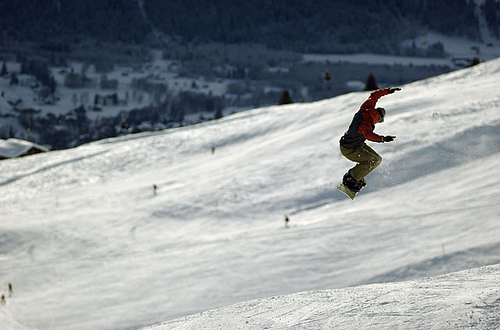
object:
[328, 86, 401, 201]
person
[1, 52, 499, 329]
snow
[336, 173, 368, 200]
snowboard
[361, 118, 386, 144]
arm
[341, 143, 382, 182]
pants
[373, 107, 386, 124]
head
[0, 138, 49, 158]
roof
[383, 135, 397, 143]
glove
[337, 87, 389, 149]
jacket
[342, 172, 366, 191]
shoes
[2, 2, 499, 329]
air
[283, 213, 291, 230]
person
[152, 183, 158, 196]
person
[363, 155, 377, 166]
knees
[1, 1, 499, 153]
mountain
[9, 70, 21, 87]
trees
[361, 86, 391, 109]
arm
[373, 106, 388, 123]
hat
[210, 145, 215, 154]
person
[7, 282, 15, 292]
person